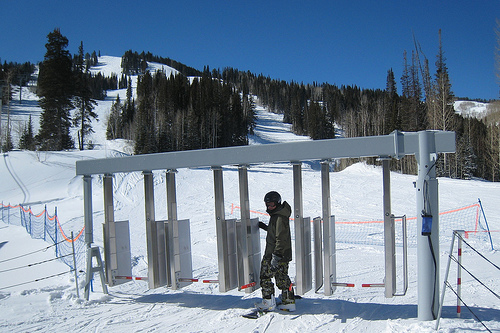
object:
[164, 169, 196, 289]
pillar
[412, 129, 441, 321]
pillar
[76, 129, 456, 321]
dividers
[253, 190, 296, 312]
man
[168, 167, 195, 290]
pillar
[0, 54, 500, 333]
snow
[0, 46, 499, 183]
forested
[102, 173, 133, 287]
pillar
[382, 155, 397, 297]
pillar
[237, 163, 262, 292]
pillar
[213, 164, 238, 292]
pillar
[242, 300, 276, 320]
snowboard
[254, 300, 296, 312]
boots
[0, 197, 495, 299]
barrier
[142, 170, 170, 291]
pillar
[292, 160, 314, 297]
pillar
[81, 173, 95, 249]
pillar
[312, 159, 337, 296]
pillar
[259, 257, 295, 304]
pants